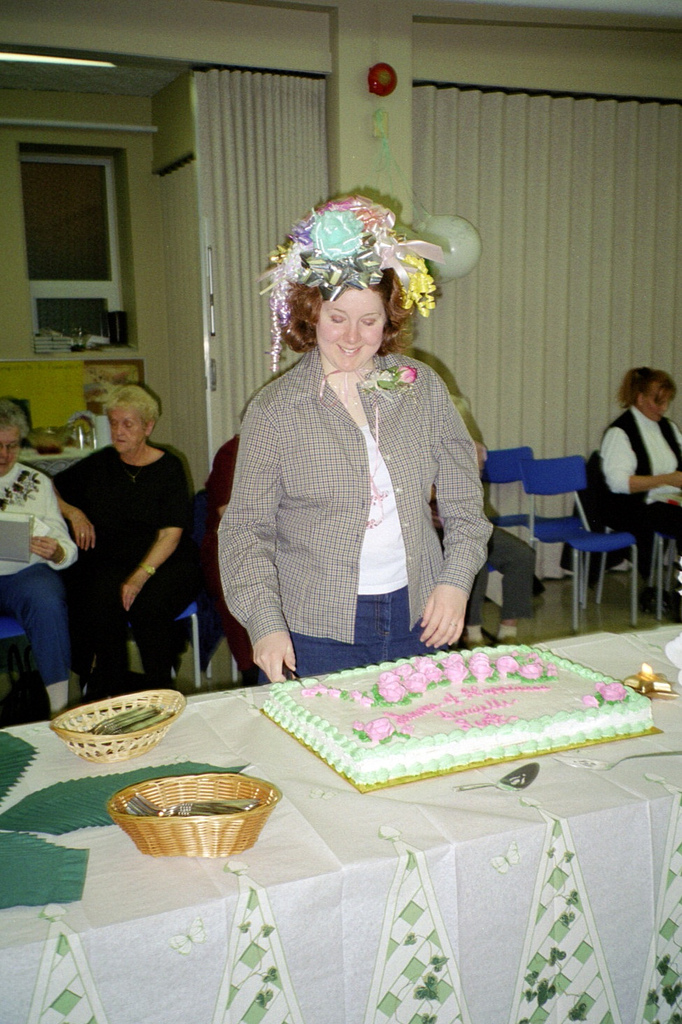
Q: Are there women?
A: Yes, there is a woman.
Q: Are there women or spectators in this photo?
A: Yes, there is a woman.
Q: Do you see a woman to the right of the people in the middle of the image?
A: Yes, there is a woman to the right of the people.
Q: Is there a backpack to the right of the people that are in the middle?
A: No, there is a woman to the right of the people.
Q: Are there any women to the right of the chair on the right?
A: Yes, there is a woman to the right of the chair.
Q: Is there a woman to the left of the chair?
A: No, the woman is to the right of the chair.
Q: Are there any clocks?
A: No, there are no clocks.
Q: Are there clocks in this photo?
A: No, there are no clocks.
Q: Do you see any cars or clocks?
A: No, there are no clocks or cars.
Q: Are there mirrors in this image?
A: No, there are no mirrors.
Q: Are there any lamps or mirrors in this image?
A: No, there are no mirrors or lamps.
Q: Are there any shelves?
A: No, there are no shelves.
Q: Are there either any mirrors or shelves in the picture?
A: No, there are no shelves or mirrors.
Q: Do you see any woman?
A: Yes, there is a woman.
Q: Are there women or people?
A: Yes, there is a woman.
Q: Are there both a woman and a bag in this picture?
A: No, there is a woman but no bags.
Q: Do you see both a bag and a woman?
A: No, there is a woman but no bags.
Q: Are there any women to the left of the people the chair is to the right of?
A: Yes, there is a woman to the left of the people.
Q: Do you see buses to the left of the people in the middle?
A: No, there is a woman to the left of the people.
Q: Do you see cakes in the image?
A: Yes, there is a cake.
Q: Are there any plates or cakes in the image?
A: Yes, there is a cake.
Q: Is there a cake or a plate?
A: Yes, there is a cake.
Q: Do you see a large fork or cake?
A: Yes, there is a large cake.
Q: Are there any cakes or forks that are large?
A: Yes, the cake is large.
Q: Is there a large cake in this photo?
A: Yes, there is a large cake.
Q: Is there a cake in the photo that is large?
A: Yes, there is a cake that is large.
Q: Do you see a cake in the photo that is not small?
A: Yes, there is a large cake.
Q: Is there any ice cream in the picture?
A: No, there is no ice cream.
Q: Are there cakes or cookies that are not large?
A: No, there is a cake but it is large.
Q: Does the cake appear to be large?
A: Yes, the cake is large.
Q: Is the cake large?
A: Yes, the cake is large.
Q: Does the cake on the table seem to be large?
A: Yes, the cake is large.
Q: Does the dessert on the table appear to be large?
A: Yes, the cake is large.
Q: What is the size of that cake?
A: The cake is large.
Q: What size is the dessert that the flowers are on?
A: The cake is large.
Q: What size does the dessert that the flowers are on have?
A: The cake has large size.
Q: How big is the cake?
A: The cake is large.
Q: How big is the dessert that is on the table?
A: The cake is large.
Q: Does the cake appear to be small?
A: No, the cake is large.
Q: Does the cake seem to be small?
A: No, the cake is large.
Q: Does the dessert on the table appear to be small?
A: No, the cake is large.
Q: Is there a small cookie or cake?
A: No, there is a cake but it is large.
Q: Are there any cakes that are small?
A: No, there is a cake but it is large.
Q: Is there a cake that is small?
A: No, there is a cake but it is large.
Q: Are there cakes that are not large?
A: No, there is a cake but it is large.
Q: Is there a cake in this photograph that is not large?
A: No, there is a cake but it is large.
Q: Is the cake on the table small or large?
A: The cake is large.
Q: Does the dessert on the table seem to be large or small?
A: The cake is large.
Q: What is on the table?
A: The cake is on the table.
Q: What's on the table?
A: The cake is on the table.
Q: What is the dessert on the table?
A: The dessert is a cake.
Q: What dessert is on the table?
A: The dessert is a cake.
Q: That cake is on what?
A: The cake is on the table.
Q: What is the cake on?
A: The cake is on the table.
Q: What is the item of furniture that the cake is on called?
A: The piece of furniture is a table.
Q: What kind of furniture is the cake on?
A: The cake is on the table.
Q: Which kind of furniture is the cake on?
A: The cake is on the table.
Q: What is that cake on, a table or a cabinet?
A: The cake is on a table.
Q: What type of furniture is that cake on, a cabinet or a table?
A: The cake is on a table.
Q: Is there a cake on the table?
A: Yes, there is a cake on the table.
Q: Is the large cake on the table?
A: Yes, the cake is on the table.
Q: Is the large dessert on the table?
A: Yes, the cake is on the table.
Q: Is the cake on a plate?
A: No, the cake is on the table.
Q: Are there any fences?
A: No, there are no fences.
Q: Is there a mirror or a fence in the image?
A: No, there are no fences or mirrors.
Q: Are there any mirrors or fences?
A: No, there are no fences or mirrors.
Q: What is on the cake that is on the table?
A: The flowers are on the cake.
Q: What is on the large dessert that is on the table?
A: The flowers are on the cake.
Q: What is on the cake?
A: The flowers are on the cake.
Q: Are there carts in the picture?
A: No, there are no carts.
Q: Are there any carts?
A: No, there are no carts.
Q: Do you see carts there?
A: No, there are no carts.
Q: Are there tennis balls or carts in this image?
A: No, there are no carts or tennis balls.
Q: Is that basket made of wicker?
A: Yes, the basket is made of wicker.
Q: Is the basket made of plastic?
A: No, the basket is made of wicker.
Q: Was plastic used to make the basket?
A: No, the basket is made of wicker.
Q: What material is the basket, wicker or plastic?
A: The basket is made of wicker.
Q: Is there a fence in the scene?
A: No, there are no fences.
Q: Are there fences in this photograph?
A: No, there are no fences.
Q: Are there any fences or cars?
A: No, there are no fences or cars.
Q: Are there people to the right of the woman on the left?
A: Yes, there are people to the right of the woman.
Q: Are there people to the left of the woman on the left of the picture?
A: No, the people are to the right of the woman.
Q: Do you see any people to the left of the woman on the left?
A: No, the people are to the right of the woman.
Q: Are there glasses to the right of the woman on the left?
A: No, there are people to the right of the woman.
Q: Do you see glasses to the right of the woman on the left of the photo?
A: No, there are people to the right of the woman.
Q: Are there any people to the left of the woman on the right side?
A: Yes, there are people to the left of the woman.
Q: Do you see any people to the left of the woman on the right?
A: Yes, there are people to the left of the woman.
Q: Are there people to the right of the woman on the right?
A: No, the people are to the left of the woman.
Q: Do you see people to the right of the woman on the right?
A: No, the people are to the left of the woman.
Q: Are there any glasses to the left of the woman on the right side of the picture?
A: No, there are people to the left of the woman.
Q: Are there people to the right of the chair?
A: No, the people are to the left of the chair.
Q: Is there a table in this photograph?
A: Yes, there is a table.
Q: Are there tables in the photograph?
A: Yes, there is a table.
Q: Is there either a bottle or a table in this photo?
A: Yes, there is a table.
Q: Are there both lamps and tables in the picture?
A: No, there is a table but no lamps.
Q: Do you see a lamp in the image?
A: No, there are no lamps.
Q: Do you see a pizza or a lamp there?
A: No, there are no lamps or pizzas.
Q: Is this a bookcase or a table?
A: This is a table.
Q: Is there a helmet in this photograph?
A: No, there are no helmets.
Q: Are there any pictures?
A: No, there are no pictures.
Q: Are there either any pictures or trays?
A: No, there are no pictures or trays.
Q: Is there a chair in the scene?
A: Yes, there is a chair.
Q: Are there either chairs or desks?
A: Yes, there is a chair.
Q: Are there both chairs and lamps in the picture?
A: No, there is a chair but no lamps.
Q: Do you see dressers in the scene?
A: No, there are no dressers.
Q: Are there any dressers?
A: No, there are no dressers.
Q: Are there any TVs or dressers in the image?
A: No, there are no dressers or tvs.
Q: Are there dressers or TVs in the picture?
A: No, there are no dressers or tvs.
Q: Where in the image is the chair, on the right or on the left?
A: The chair is on the right of the image.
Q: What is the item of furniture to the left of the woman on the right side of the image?
A: The piece of furniture is a chair.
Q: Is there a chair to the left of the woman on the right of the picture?
A: Yes, there is a chair to the left of the woman.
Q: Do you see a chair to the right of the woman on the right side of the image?
A: No, the chair is to the left of the woman.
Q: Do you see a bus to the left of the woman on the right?
A: No, there is a chair to the left of the woman.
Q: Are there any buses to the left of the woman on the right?
A: No, there is a chair to the left of the woman.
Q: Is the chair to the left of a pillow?
A: No, the chair is to the left of a woman.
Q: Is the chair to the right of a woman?
A: No, the chair is to the left of a woman.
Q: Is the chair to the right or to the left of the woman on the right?
A: The chair is to the left of the woman.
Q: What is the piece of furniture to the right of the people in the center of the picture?
A: The piece of furniture is a chair.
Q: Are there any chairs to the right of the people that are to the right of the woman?
A: Yes, there is a chair to the right of the people.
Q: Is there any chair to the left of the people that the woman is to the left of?
A: No, the chair is to the right of the people.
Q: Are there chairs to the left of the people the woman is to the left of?
A: No, the chair is to the right of the people.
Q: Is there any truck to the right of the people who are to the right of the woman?
A: No, there is a chair to the right of the people.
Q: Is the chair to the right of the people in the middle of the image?
A: Yes, the chair is to the right of the people.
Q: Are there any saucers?
A: No, there are no saucers.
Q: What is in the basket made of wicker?
A: The silverware is in the basket.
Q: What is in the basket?
A: The silverware is in the basket.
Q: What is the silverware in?
A: The silverware is in the basket.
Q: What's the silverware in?
A: The silverware is in the basket.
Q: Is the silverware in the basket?
A: Yes, the silverware is in the basket.